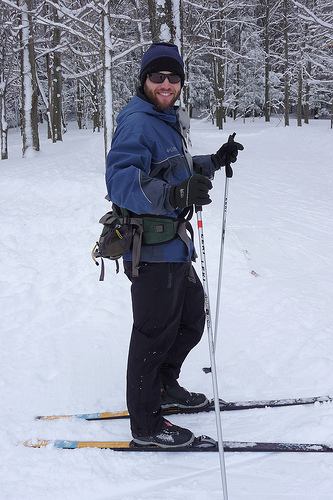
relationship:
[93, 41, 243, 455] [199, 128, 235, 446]
skier wears skis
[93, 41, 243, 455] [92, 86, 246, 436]
skier wears clothes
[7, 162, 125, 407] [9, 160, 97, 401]
snow on ground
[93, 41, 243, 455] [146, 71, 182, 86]
skier wears glasses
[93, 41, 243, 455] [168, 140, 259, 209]
skier wears gloves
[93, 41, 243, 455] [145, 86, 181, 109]
skier has beard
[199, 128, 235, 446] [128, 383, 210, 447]
skis on man's feet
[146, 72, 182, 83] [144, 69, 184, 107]
glasses are on man's face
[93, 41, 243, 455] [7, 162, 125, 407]
skier in snow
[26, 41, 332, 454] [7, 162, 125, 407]
skier on flat snow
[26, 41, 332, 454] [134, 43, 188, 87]
skier wearing hat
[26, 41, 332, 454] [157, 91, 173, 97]
skier has grin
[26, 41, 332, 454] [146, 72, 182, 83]
skier wears glasses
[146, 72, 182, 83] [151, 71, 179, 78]
glasses have frames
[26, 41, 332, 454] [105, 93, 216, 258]
skier wears jacket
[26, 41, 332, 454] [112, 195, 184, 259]
skier wears man's waist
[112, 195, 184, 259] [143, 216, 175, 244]
man's waist has fanny pack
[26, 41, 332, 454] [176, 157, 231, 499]
skier holds poles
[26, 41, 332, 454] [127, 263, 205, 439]
skier wears pants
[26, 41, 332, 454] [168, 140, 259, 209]
skier wears gloves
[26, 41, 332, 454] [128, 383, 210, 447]
skier wears shoes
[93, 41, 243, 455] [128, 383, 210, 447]
skier wears shoes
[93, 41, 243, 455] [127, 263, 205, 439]
skier wearing pants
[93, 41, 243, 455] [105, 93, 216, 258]
skier wearing jacket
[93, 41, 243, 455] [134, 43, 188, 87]
skier wearing beanie hat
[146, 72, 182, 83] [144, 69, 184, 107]
glasses on man's face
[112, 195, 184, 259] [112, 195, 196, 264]
man's waist on man's waist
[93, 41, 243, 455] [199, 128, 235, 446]
skier holds ski poles